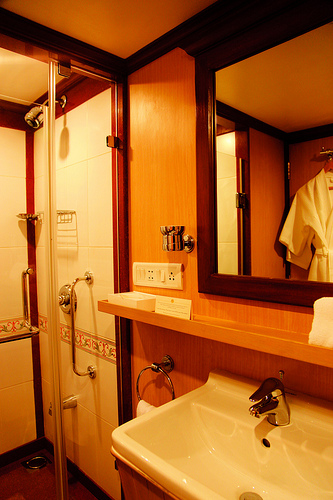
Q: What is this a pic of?
A: Hotel room.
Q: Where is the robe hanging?
A: Back of door.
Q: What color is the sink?
A: White.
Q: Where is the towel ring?
A: Beside the sink.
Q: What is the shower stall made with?
A: Tiles.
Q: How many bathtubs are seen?
A: None.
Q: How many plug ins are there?
A: 2.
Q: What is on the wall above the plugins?
A: Wall sconce.